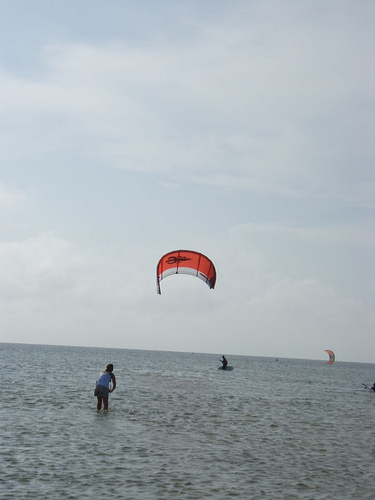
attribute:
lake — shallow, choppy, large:
[26, 359, 371, 492]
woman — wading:
[80, 362, 125, 411]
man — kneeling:
[211, 349, 226, 372]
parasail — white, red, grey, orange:
[146, 244, 229, 296]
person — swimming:
[266, 355, 297, 371]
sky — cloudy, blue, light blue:
[26, 33, 347, 277]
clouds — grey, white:
[111, 73, 276, 153]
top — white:
[98, 372, 112, 388]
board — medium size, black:
[218, 364, 237, 374]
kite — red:
[161, 240, 225, 293]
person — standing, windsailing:
[215, 342, 238, 385]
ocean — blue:
[14, 317, 371, 456]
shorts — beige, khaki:
[88, 387, 112, 400]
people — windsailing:
[59, 336, 249, 430]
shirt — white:
[98, 371, 112, 393]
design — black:
[168, 253, 200, 272]